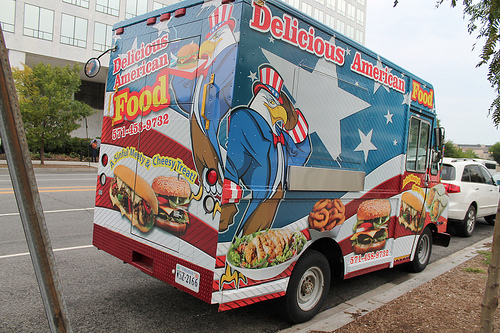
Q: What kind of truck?
A: Food truck.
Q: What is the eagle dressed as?
A: Uncle sam.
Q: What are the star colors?
A: White.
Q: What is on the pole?
A: Sign.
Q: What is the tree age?
A: Young.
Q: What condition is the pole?
A: Rusted.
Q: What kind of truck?
A: Food truck.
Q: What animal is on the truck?
A: Eagle.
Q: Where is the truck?
A: Street.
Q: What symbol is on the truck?
A: Stars.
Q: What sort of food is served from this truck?
A: American.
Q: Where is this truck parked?
A: Near the curb.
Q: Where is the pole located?
A: On the street.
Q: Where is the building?
A: Near the tree.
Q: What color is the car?
A: White.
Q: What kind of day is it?
A: Cloudy.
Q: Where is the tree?
A: Near the curb.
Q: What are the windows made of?
A: Glass.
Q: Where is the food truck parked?
A: The street.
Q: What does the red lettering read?
A: Delicious american.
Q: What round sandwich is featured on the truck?
A: A hamburger.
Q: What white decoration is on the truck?
A: A star.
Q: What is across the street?
A: High rise building.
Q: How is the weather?
A: Clear.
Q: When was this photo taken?
A: Day time.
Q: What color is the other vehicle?
A: White.